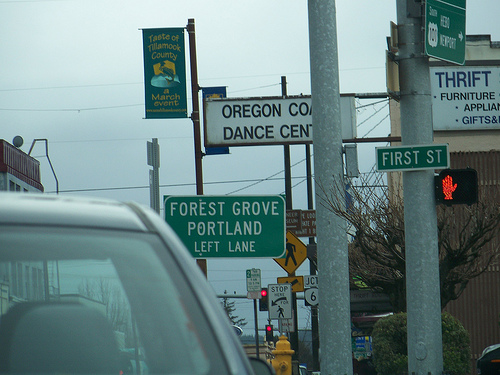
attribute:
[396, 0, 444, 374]
pole — grey, sturdy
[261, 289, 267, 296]
light — is red, glowing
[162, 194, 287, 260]
sign — green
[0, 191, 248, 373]
car — grey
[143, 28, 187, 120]
flag — tillamock county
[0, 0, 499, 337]
sky — blue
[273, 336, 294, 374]
pump — yellow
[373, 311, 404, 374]
plant — green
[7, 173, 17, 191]
window — white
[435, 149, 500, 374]
wall — red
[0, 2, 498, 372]
picture — daytime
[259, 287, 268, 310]
signal — red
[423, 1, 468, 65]
sign — directions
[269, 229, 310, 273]
sign — caution, stop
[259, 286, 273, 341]
lights — is red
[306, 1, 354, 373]
pole — sturdy